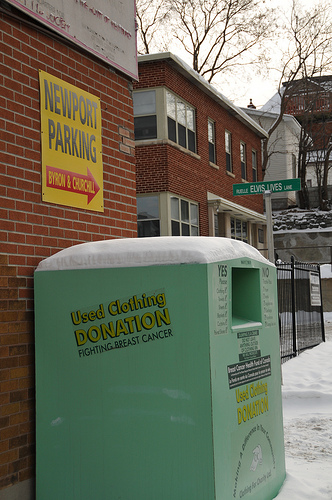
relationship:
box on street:
[31, 235, 286, 498] [275, 326, 330, 496]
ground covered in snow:
[271, 296, 321, 489] [278, 347, 326, 485]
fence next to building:
[277, 261, 326, 365] [133, 50, 276, 265]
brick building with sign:
[0, 0, 138, 497] [42, 73, 106, 210]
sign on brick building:
[42, 73, 106, 210] [0, 0, 138, 497]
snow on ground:
[287, 351, 326, 423] [289, 361, 325, 481]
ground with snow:
[289, 361, 325, 481] [287, 351, 326, 423]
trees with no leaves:
[177, 5, 275, 90] [298, 28, 325, 58]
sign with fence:
[308, 267, 326, 311] [277, 261, 326, 365]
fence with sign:
[277, 261, 326, 365] [308, 267, 326, 311]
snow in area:
[33, 236, 277, 271] [298, 351, 327, 497]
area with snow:
[298, 351, 327, 497] [33, 236, 277, 271]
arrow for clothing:
[45, 166, 101, 206] [246, 441, 267, 476]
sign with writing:
[42, 73, 106, 210] [41, 76, 99, 130]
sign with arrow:
[42, 73, 106, 210] [45, 156, 102, 206]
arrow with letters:
[45, 166, 101, 206] [56, 287, 186, 350]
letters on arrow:
[56, 287, 186, 350] [45, 166, 101, 206]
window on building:
[164, 87, 179, 144] [133, 50, 274, 287]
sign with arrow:
[42, 73, 106, 210] [45, 166, 101, 206]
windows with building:
[131, 83, 208, 159] [139, 45, 266, 242]